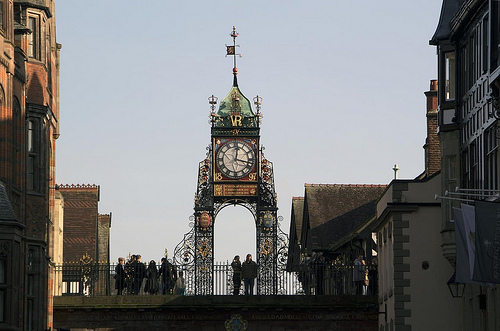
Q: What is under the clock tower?
A: A couple.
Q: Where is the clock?
A: Over metal arched tower doorway.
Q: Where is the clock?
A: On the arch.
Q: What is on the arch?
A: A clock.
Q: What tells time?
A: A clock.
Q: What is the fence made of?
A: Metal.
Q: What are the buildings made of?
A: Brick.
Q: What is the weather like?
A: Chilly.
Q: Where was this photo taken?
A: Outside near the clock.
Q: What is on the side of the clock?
A: Buildings.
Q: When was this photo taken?
A: During the day.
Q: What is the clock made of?
A: Concrete.